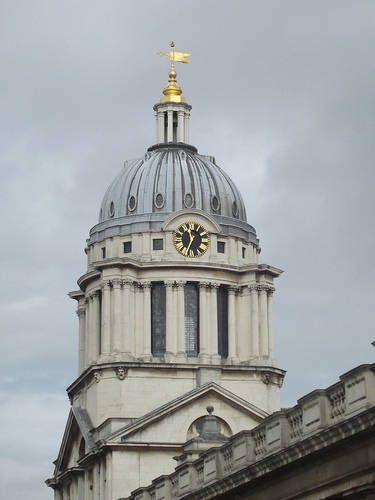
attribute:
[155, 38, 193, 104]
piece — gold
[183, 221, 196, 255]
time — 11:40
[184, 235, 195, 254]
hand — gold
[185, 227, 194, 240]
hand — gold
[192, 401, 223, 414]
ball — round, small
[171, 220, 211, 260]
clock — gold, round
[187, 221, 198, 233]
numeral — roman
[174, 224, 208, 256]
face — black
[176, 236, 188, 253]
numbers — gold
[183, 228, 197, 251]
hand — gold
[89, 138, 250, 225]
dome — gray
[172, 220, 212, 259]
numbers — Roman letters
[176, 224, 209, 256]
background — black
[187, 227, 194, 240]
hand — yellow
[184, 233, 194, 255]
hand — yellow